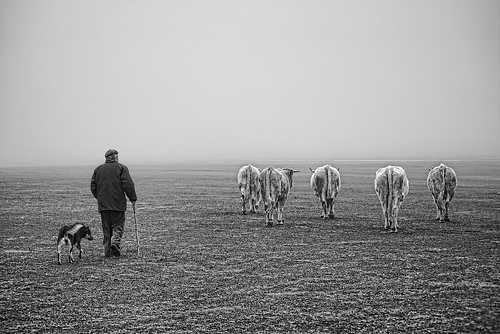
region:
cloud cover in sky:
[5, 3, 497, 163]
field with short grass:
[0, 163, 499, 332]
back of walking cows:
[237, 163, 457, 230]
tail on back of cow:
[383, 166, 396, 203]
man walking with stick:
[90, 148, 140, 257]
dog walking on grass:
[55, 222, 92, 263]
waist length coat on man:
[88, 163, 135, 213]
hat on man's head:
[103, 149, 120, 160]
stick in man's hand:
[130, 199, 142, 255]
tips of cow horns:
[308, 165, 343, 175]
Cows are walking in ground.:
[221, 158, 472, 227]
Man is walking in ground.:
[84, 146, 152, 255]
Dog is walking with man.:
[46, 199, 100, 266]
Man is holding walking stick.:
[123, 186, 160, 262]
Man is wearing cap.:
[86, 145, 145, 190]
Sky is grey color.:
[83, 22, 261, 92]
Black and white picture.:
[21, 38, 477, 308]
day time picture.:
[28, 36, 457, 297]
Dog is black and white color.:
[46, 213, 103, 257]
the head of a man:
[86, 140, 139, 177]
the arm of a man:
[114, 163, 146, 207]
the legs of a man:
[86, 193, 151, 261]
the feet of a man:
[85, 216, 167, 270]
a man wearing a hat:
[90, 125, 147, 178]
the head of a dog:
[79, 213, 101, 248]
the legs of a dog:
[54, 233, 96, 270]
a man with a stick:
[84, 160, 182, 261]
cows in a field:
[201, 154, 461, 246]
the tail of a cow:
[371, 165, 413, 208]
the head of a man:
[91, 132, 154, 174]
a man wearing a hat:
[81, 134, 151, 217]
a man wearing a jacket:
[70, 135, 174, 227]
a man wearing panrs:
[89, 190, 160, 259]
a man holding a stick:
[79, 143, 181, 252]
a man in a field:
[81, 131, 181, 261]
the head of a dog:
[66, 218, 103, 240]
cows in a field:
[245, 119, 448, 226]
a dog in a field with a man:
[42, 211, 110, 268]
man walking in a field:
[91, 141, 148, 263]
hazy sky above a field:
[2, 2, 499, 175]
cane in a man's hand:
[130, 198, 150, 261]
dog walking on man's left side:
[49, 215, 96, 267]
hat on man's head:
[103, 147, 118, 156]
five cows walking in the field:
[222, 152, 466, 239]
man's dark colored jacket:
[85, 160, 137, 214]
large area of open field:
[1, 164, 498, 332]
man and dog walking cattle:
[48, 146, 142, 264]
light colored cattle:
[229, 158, 459, 236]